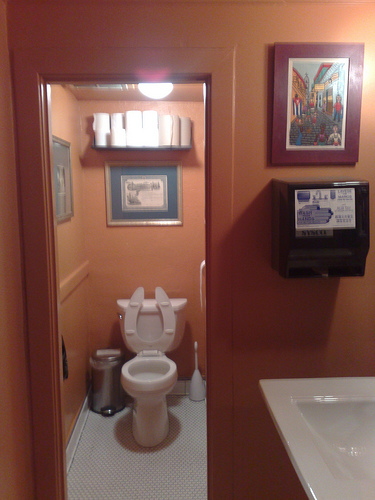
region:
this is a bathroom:
[46, 230, 227, 380]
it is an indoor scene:
[7, 109, 297, 404]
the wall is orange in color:
[107, 247, 160, 273]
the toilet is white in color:
[114, 289, 181, 427]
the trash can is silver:
[89, 349, 122, 422]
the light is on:
[119, 74, 203, 123]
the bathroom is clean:
[59, 291, 168, 492]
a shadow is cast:
[226, 189, 334, 357]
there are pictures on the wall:
[88, 154, 216, 287]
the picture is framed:
[92, 152, 199, 254]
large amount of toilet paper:
[88, 108, 160, 147]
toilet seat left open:
[112, 283, 178, 446]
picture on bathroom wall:
[101, 158, 186, 229]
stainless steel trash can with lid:
[83, 344, 125, 418]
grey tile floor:
[67, 377, 204, 498]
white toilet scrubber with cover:
[186, 338, 205, 402]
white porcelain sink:
[258, 374, 374, 498]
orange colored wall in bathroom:
[78, 100, 203, 380]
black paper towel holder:
[270, 177, 368, 283]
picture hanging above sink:
[270, 37, 365, 165]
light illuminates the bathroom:
[135, 80, 182, 100]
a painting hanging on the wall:
[264, 38, 360, 164]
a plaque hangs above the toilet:
[98, 160, 188, 231]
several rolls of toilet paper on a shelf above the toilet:
[90, 108, 197, 145]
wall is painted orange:
[94, 233, 186, 278]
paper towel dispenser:
[270, 176, 369, 284]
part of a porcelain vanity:
[261, 378, 363, 494]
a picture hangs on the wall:
[47, 130, 70, 220]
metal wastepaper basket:
[84, 345, 116, 409]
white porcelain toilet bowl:
[119, 285, 178, 453]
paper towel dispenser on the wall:
[265, 170, 373, 287]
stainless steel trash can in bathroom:
[80, 344, 130, 418]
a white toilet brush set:
[182, 335, 209, 409]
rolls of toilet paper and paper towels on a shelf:
[85, 106, 195, 155]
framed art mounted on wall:
[266, 38, 366, 169]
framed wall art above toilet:
[98, 156, 190, 233]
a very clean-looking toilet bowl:
[110, 278, 190, 453]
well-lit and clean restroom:
[6, 38, 244, 498]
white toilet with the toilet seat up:
[105, 281, 193, 457]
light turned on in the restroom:
[133, 73, 177, 102]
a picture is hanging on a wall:
[274, 44, 364, 168]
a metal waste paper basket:
[89, 350, 125, 418]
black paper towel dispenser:
[275, 179, 369, 284]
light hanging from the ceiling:
[136, 82, 178, 101]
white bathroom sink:
[266, 376, 373, 496]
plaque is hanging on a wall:
[106, 162, 183, 227]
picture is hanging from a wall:
[48, 137, 80, 221]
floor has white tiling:
[83, 445, 155, 491]